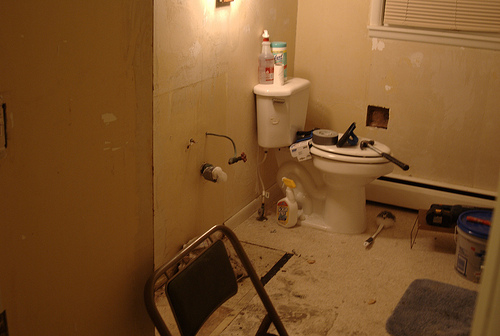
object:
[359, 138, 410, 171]
hammer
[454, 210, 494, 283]
bucket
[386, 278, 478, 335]
rug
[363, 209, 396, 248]
toilet brush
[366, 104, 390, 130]
hole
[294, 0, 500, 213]
wall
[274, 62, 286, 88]
toilet paper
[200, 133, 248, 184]
plumbing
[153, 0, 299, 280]
wall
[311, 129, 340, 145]
duct tape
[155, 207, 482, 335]
floor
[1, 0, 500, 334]
bathroom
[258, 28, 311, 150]
objects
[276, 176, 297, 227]
spray bottle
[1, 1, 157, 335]
wall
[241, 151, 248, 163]
water knob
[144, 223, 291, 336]
stool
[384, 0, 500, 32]
blinds